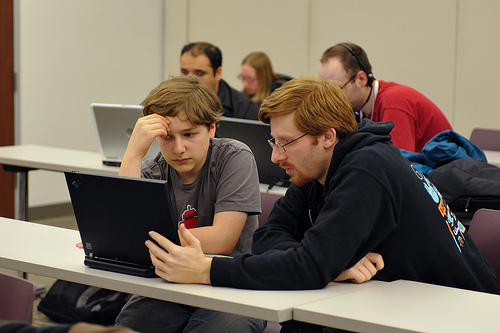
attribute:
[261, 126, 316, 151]
eyeglasses — brown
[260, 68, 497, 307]
person — white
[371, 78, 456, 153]
sweater — red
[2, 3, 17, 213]
door — brown, wooden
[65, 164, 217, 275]
laptop — black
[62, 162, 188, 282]
computer — black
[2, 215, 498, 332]
tables — long